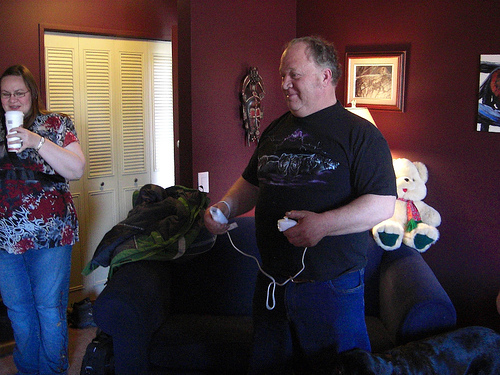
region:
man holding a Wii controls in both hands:
[201, 33, 401, 351]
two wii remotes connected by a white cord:
[207, 205, 311, 311]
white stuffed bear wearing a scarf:
[373, 157, 443, 254]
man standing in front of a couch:
[79, 36, 456, 373]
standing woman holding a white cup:
[0, 61, 87, 373]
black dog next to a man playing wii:
[201, 34, 499, 374]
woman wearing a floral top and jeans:
[0, 62, 87, 374]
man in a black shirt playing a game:
[205, 34, 407, 353]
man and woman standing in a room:
[2, 21, 400, 373]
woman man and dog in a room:
[0, 34, 499, 374]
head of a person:
[265, 32, 342, 127]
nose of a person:
[276, 73, 293, 93]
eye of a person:
[277, 71, 304, 79]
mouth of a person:
[279, 82, 307, 109]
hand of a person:
[277, 209, 324, 257]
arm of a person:
[223, 176, 271, 214]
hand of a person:
[199, 208, 234, 236]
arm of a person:
[39, 118, 81, 203]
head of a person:
[257, 23, 348, 114]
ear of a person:
[316, 61, 346, 98]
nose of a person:
[273, 68, 303, 92]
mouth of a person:
[285, 89, 305, 107]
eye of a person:
[289, 61, 309, 81]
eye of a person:
[275, 65, 293, 87]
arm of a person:
[203, 162, 251, 254]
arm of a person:
[280, 186, 397, 261]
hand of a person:
[272, 176, 346, 263]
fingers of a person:
[280, 196, 328, 266]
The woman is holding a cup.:
[2, 60, 87, 372]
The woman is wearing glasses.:
[1, 55, 91, 374]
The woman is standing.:
[2, 63, 93, 373]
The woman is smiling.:
[0, 57, 90, 373]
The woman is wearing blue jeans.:
[0, 58, 92, 373]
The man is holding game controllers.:
[198, 29, 401, 374]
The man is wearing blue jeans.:
[198, 30, 400, 373]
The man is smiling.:
[196, 23, 396, 373]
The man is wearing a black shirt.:
[193, 14, 399, 374]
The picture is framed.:
[339, 30, 416, 120]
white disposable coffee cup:
[5, 108, 26, 151]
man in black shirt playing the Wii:
[205, 30, 400, 275]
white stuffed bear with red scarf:
[392, 155, 442, 250]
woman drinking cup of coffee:
[2, 63, 66, 190]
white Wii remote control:
[209, 205, 229, 229]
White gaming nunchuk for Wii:
[277, 215, 297, 231]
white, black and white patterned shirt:
[3, 191, 68, 238]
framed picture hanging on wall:
[349, 43, 407, 110]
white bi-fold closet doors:
[84, 44, 156, 179]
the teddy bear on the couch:
[376, 155, 436, 256]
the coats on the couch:
[100, 192, 210, 269]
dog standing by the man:
[338, 331, 497, 371]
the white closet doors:
[47, 31, 152, 300]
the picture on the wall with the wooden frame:
[340, 40, 414, 124]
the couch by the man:
[98, 217, 448, 372]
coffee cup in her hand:
[2, 107, 31, 154]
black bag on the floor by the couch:
[84, 333, 126, 373]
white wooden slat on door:
[122, 165, 145, 172]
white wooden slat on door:
[124, 154, 144, 163]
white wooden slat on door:
[123, 125, 143, 130]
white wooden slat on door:
[120, 118, 144, 126]